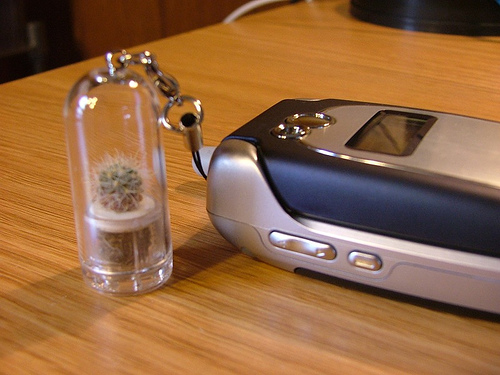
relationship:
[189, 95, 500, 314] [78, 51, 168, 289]
call phone chained to glass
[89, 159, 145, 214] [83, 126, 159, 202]
cactus has thorns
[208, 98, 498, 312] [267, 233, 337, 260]
call phone has button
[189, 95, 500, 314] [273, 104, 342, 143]
call phone contains lens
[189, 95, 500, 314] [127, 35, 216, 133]
call phone contains chain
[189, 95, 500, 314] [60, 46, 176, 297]
call phone contains glass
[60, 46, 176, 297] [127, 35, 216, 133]
glass attached by chain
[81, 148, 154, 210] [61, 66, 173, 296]
ball in container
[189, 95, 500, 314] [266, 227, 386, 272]
call phone has buttons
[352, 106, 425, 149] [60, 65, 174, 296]
glass of a glass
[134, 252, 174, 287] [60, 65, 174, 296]
edge of a glass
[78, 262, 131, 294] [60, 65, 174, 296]
edge of a glass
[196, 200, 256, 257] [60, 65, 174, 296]
edge of a glass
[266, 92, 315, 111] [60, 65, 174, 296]
edge of a glass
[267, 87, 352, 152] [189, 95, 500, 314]
camera on front of call phone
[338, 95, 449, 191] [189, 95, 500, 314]
screen on front of call phone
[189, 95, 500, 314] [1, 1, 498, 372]
call phone placed on table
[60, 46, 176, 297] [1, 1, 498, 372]
glass placed on table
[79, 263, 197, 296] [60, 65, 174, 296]
edge lining glass